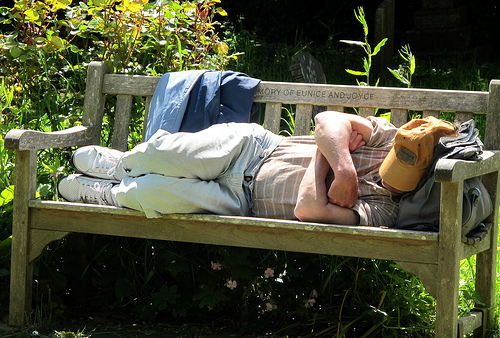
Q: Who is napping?
A: Elderly man.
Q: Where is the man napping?
A: Bench.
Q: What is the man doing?
A: Sleeping.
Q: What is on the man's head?
A: A hat.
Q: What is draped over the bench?
A: A jacket.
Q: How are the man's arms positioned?
A: Crossed.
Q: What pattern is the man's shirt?
A: Striped.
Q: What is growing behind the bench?
A: Trees.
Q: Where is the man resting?
A: A bench.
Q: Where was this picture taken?
A: A park.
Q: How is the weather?
A: Sunny.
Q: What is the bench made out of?
A: Wood.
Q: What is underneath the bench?
A: Bush.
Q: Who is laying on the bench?
A: Male.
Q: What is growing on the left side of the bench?
A: Rose bush.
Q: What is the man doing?
A: Sleeping.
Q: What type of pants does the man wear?
A: White slacks.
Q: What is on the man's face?
A: Hat.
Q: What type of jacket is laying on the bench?
A: Denim.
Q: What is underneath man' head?
A: Backpack.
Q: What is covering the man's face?
A: A hat.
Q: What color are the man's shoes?
A: White.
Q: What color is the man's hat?
A: Yellow.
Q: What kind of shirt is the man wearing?
A: Striped.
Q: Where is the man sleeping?
A: On a bench.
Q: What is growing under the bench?
A: Flowers.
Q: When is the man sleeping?
A: Daytime.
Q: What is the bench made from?
A: Wood.